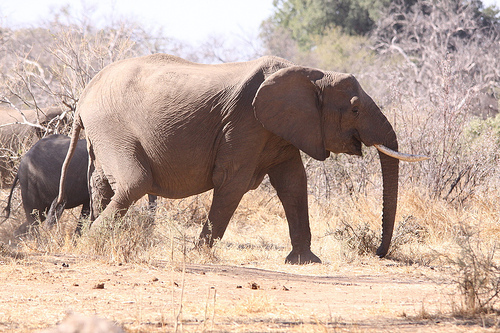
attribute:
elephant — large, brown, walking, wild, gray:
[40, 26, 431, 267]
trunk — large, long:
[362, 141, 412, 286]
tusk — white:
[362, 139, 406, 263]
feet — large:
[65, 209, 333, 266]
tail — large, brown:
[41, 117, 95, 219]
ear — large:
[232, 60, 341, 165]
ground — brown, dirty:
[1, 206, 499, 332]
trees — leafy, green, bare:
[1, 2, 499, 195]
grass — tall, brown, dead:
[22, 202, 465, 267]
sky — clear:
[7, 0, 275, 36]